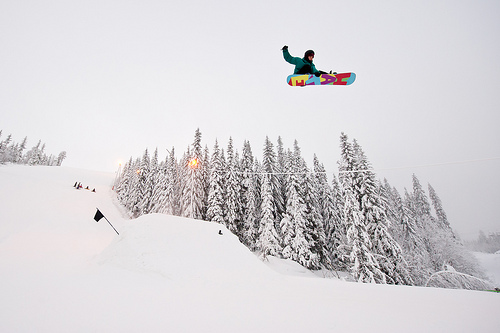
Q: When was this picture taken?
A: Daytime.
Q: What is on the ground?
A: Snow.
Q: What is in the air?
A: A snowboarder.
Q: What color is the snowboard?
A: Red, yellow and blue.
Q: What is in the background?
A: Trees.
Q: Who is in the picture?
A: A man.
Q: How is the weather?
A: Clear.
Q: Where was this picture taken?
A: A ski slope.